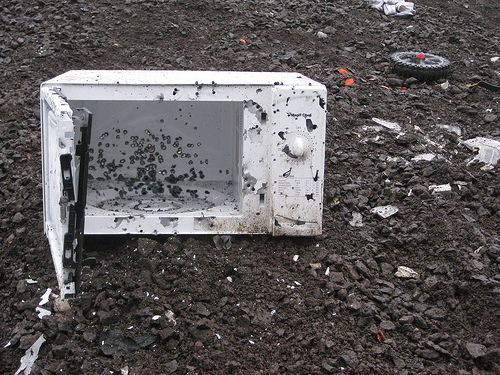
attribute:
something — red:
[397, 85, 408, 92]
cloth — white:
[371, 0, 414, 20]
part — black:
[75, 100, 122, 272]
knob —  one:
[283, 129, 317, 164]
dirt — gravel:
[271, 250, 491, 364]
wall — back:
[102, 102, 230, 189]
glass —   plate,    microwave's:
[98, 180, 223, 264]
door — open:
[30, 82, 90, 307]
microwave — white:
[40, 63, 324, 240]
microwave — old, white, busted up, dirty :
[39, 68, 329, 305]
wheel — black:
[371, 42, 472, 98]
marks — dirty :
[156, 116, 166, 123]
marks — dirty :
[175, 107, 182, 113]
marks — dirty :
[191, 124, 199, 131]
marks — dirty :
[186, 103, 197, 110]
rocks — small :
[155, 287, 307, 363]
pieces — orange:
[331, 65, 401, 108]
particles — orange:
[328, 60, 408, 93]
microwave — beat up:
[44, 65, 301, 228]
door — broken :
[37, 87, 92, 303]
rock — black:
[194, 300, 209, 317]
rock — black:
[219, 282, 234, 293]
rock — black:
[94, 307, 111, 319]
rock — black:
[137, 236, 159, 255]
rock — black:
[192, 337, 205, 350]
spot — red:
[416, 52, 425, 59]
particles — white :
[345, 108, 475, 218]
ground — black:
[2, 9, 496, 373]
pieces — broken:
[350, 116, 498, 283]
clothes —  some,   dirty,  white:
[370, 0, 417, 21]